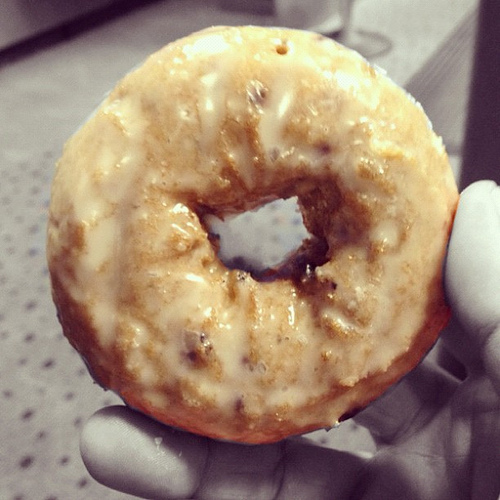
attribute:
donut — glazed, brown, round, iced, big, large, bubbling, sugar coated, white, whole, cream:
[47, 25, 459, 446]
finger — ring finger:
[80, 405, 373, 499]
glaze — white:
[47, 26, 460, 445]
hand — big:
[80, 179, 500, 498]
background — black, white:
[0, 1, 499, 499]